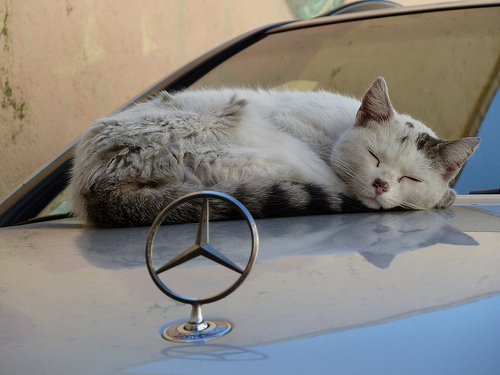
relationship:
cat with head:
[72, 76, 482, 224] [339, 87, 453, 207]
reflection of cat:
[89, 230, 447, 277] [72, 76, 482, 224]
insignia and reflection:
[144, 183, 281, 313] [165, 340, 274, 372]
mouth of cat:
[360, 188, 391, 221] [72, 76, 482, 224]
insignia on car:
[144, 183, 281, 313] [382, 260, 488, 350]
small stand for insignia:
[184, 306, 216, 335] [144, 183, 281, 313]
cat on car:
[72, 76, 482, 224] [382, 260, 488, 350]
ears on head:
[355, 71, 478, 176] [339, 87, 453, 207]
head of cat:
[339, 87, 453, 207] [72, 76, 482, 224]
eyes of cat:
[373, 138, 425, 192] [72, 76, 482, 224]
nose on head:
[372, 178, 391, 202] [339, 87, 453, 207]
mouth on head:
[360, 188, 391, 221] [339, 87, 453, 207]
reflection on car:
[89, 230, 447, 277] [382, 260, 488, 350]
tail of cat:
[105, 185, 347, 223] [72, 76, 482, 224]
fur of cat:
[159, 93, 247, 99] [72, 76, 482, 224]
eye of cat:
[366, 145, 402, 176] [72, 76, 482, 224]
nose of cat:
[372, 178, 391, 202] [72, 76, 482, 224]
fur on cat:
[159, 93, 247, 99] [72, 76, 482, 224]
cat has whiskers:
[72, 76, 482, 224] [334, 156, 372, 187]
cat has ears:
[72, 76, 482, 224] [355, 71, 478, 176]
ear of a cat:
[345, 81, 395, 124] [72, 76, 482, 224]